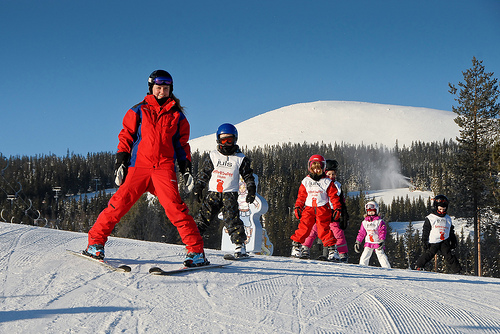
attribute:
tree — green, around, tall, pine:
[0, 140, 498, 277]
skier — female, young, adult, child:
[87, 67, 211, 269]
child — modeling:
[194, 123, 256, 259]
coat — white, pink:
[355, 214, 387, 247]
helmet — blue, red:
[216, 121, 238, 146]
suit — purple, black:
[87, 93, 203, 253]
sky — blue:
[1, 1, 500, 162]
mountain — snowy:
[261, 98, 430, 138]